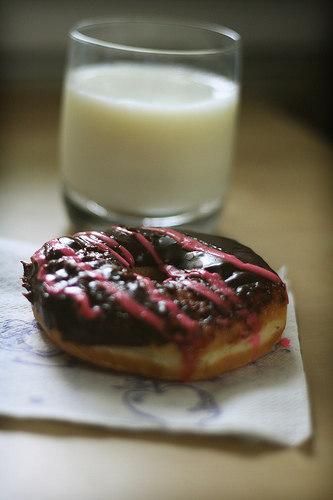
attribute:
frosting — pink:
[115, 279, 160, 311]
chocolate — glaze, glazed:
[238, 260, 278, 304]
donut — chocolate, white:
[14, 209, 265, 411]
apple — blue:
[136, 378, 223, 434]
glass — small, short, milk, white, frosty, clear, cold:
[37, 19, 257, 238]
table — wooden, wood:
[242, 121, 311, 206]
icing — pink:
[165, 243, 216, 265]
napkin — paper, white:
[233, 348, 300, 439]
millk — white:
[78, 78, 202, 150]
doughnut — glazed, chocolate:
[200, 261, 259, 324]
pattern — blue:
[154, 381, 219, 421]